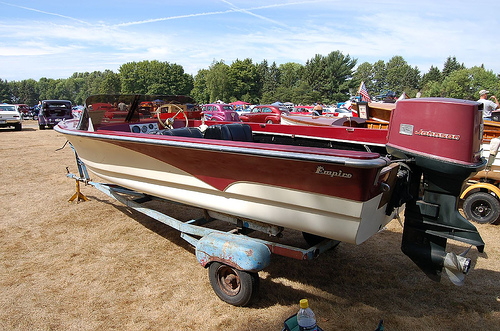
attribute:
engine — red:
[377, 88, 499, 197]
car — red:
[237, 105, 279, 125]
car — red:
[160, 101, 203, 123]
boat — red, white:
[58, 91, 486, 290]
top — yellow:
[296, 297, 311, 309]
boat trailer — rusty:
[62, 166, 341, 307]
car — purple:
[197, 100, 242, 124]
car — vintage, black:
[36, 92, 87, 137]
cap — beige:
[477, 88, 490, 95]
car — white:
[0, 104, 20, 127]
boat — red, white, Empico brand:
[61, 83, 491, 312]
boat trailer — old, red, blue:
[33, 92, 482, 273]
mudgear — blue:
[183, 227, 270, 277]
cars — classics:
[189, 95, 351, 122]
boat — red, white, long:
[39, 64, 488, 314]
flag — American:
[360, 77, 377, 112]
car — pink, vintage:
[202, 98, 238, 121]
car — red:
[239, 98, 288, 123]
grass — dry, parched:
[1, 122, 497, 329]